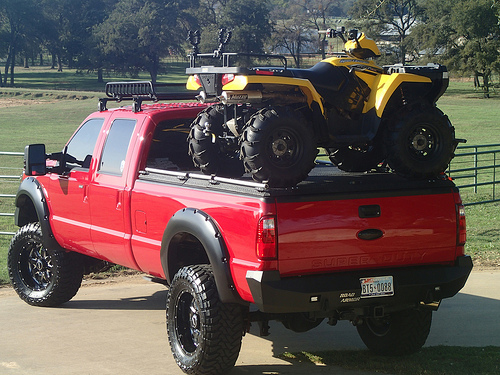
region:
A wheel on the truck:
[160, 272, 257, 354]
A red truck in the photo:
[12, 99, 463, 311]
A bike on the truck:
[175, 51, 462, 173]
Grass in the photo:
[21, 96, 56, 144]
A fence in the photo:
[456, 126, 498, 198]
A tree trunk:
[87, 68, 113, 83]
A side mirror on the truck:
[12, 131, 53, 188]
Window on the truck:
[72, 114, 127, 175]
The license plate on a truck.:
[358, 273, 395, 296]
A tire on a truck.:
[165, 259, 247, 374]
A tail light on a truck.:
[254, 213, 279, 263]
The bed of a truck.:
[129, 165, 473, 305]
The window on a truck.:
[90, 115, 140, 187]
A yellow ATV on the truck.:
[184, 23, 459, 188]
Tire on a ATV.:
[236, 102, 320, 188]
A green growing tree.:
[396, 0, 498, 97]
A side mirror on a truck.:
[24, 141, 65, 179]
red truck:
[8, 80, 478, 374]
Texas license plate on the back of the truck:
[351, 271, 411, 303]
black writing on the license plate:
[359, 279, 396, 296]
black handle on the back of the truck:
[353, 228, 385, 241]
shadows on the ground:
[67, 282, 498, 369]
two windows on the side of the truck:
[56, 110, 138, 188]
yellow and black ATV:
[171, 7, 468, 182]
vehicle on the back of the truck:
[157, 12, 469, 204]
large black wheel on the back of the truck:
[152, 262, 242, 374]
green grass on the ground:
[3, 58, 497, 300]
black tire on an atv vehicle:
[237, 97, 324, 191]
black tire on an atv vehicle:
[385, 98, 458, 180]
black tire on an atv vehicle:
[185, 97, 250, 179]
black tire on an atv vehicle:
[324, 145, 389, 175]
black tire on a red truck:
[0, 218, 82, 312]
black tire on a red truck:
[157, 263, 249, 373]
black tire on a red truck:
[348, 300, 438, 356]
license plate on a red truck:
[353, 272, 398, 301]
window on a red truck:
[91, 113, 140, 180]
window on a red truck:
[55, 113, 108, 175]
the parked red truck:
[6, 78, 473, 373]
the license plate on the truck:
[360, 275, 393, 298]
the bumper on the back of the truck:
[245, 255, 472, 314]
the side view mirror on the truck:
[23, 143, 64, 175]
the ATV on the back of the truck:
[185, 24, 467, 184]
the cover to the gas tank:
[133, 210, 147, 232]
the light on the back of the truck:
[256, 215, 277, 260]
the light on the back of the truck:
[455, 202, 466, 247]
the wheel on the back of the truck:
[165, 263, 244, 373]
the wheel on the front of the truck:
[5, 220, 83, 306]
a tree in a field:
[413, 1, 498, 95]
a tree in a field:
[352, 2, 424, 67]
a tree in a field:
[293, 4, 347, 66]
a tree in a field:
[213, 3, 279, 70]